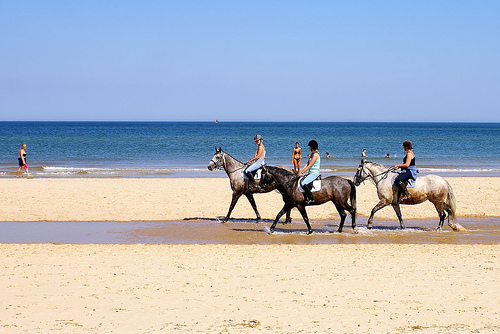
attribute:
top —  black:
[407, 151, 410, 164]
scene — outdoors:
[5, 10, 496, 310]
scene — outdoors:
[10, 8, 464, 332]